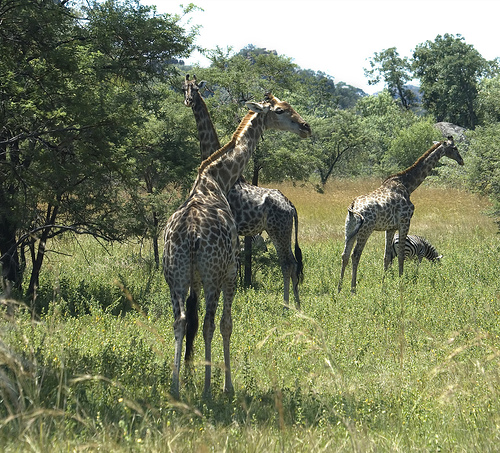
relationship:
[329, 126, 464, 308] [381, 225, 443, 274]
giraffe is next to zebra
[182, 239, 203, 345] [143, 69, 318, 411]
tail is on animal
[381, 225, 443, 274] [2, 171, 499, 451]
zebra eating grass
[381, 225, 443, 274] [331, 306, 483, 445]
zebra eating grass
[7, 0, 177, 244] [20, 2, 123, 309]
leaves are on trees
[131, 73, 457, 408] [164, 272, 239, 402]
giraffe has legs